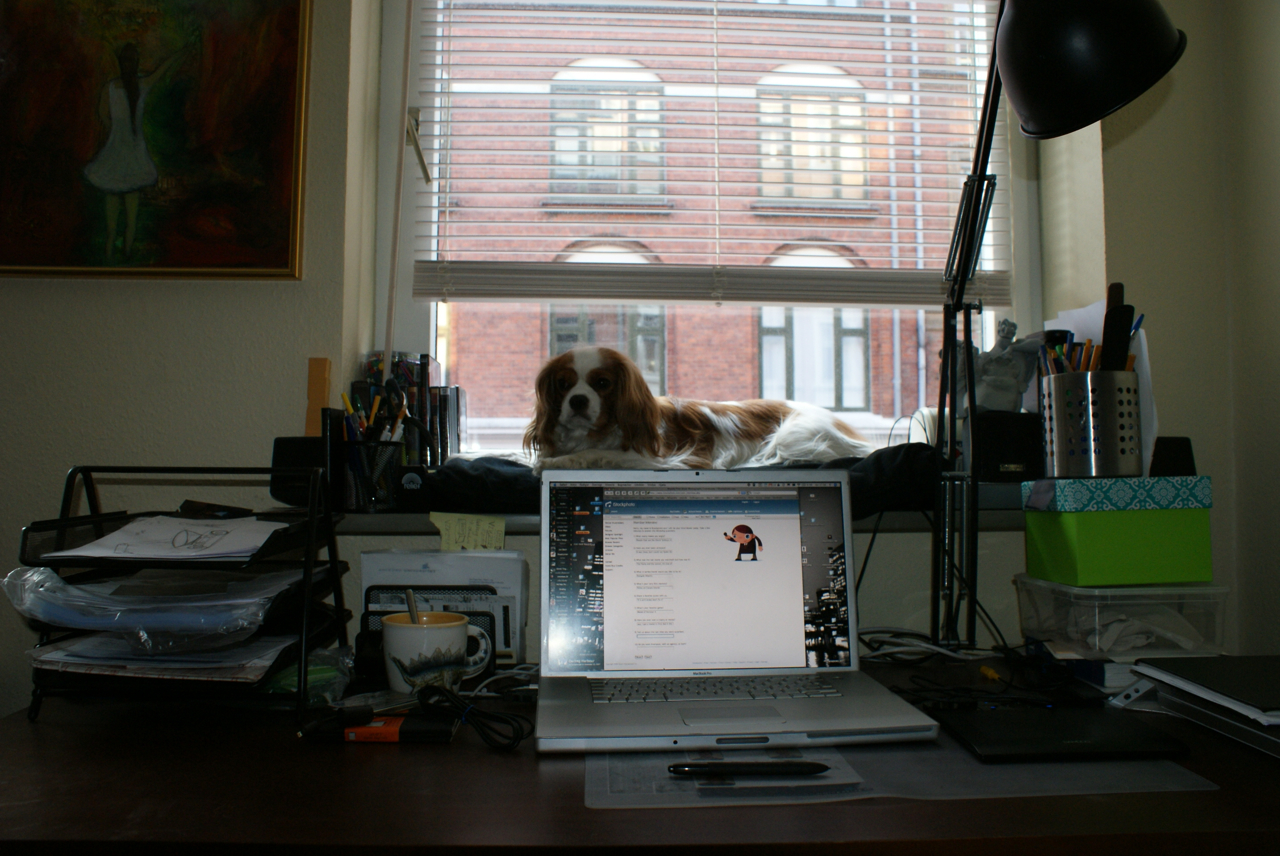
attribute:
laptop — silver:
[518, 478, 953, 746]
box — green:
[1014, 471, 1266, 566]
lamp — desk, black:
[902, 28, 1192, 675]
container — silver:
[1014, 268, 1211, 483]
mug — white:
[383, 619, 468, 695]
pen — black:
[669, 756, 826, 776]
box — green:
[1023, 470, 1242, 585]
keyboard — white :
[541, 673, 935, 751]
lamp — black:
[923, 0, 1191, 672]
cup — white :
[380, 606, 493, 693]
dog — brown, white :
[522, 342, 871, 470]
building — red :
[440, 2, 981, 453]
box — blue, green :
[1018, 470, 1224, 592]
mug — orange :
[382, 607, 493, 680]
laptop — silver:
[541, 467, 939, 752]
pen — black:
[665, 756, 833, 777]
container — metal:
[1042, 364, 1140, 475]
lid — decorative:
[1027, 471, 1213, 505]